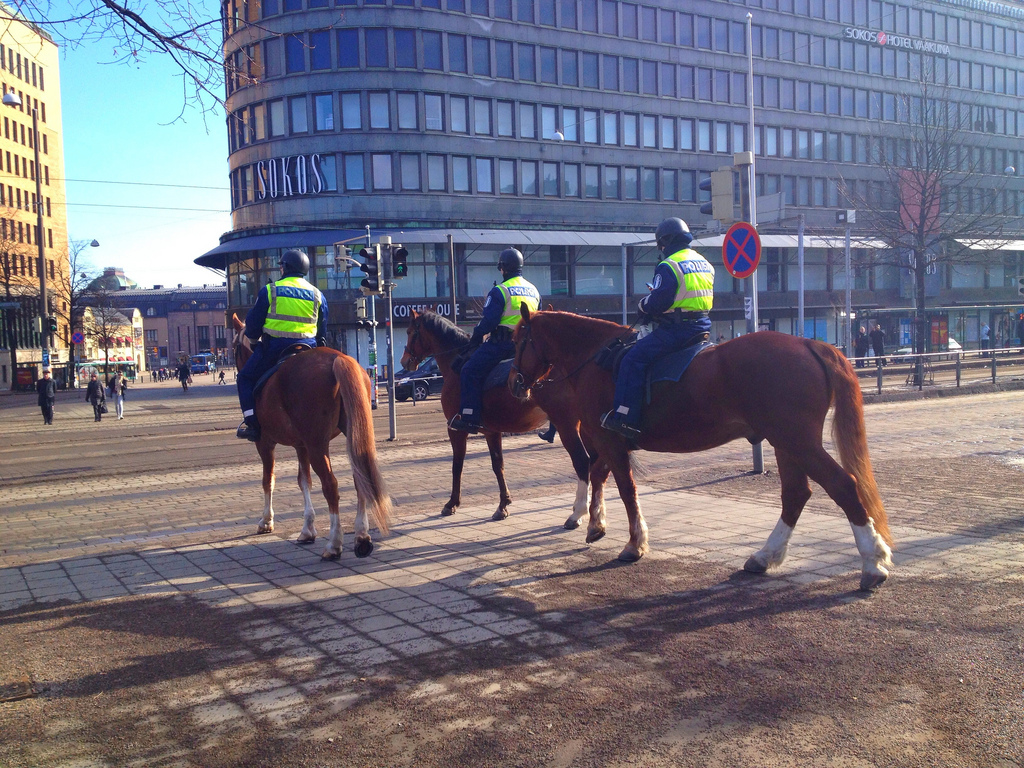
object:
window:
[263, 97, 291, 139]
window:
[341, 91, 361, 131]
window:
[396, 90, 420, 128]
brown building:
[222, 2, 1024, 241]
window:
[514, 103, 534, 139]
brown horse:
[510, 301, 901, 592]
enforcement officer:
[596, 216, 715, 442]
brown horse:
[219, 313, 400, 565]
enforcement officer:
[237, 250, 331, 439]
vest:
[239, 248, 332, 340]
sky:
[0, 0, 234, 291]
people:
[35, 369, 130, 427]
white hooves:
[564, 478, 898, 593]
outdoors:
[0, 45, 1018, 766]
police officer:
[232, 246, 331, 443]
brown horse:
[399, 304, 596, 529]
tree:
[816, 77, 1021, 386]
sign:
[721, 220, 761, 279]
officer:
[597, 214, 718, 443]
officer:
[445, 248, 545, 436]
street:
[2, 346, 1024, 766]